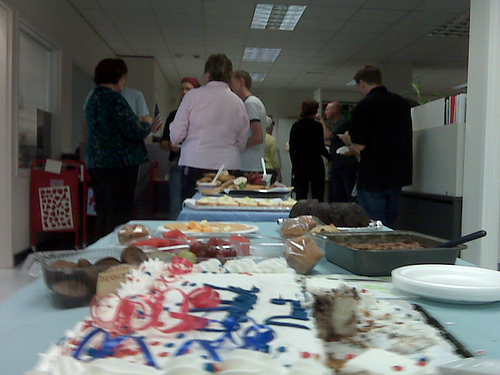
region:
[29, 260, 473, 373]
a white decorated sheet cake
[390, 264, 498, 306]
a stack of disposable plates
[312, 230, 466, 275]
a square metal pan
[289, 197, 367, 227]
a chocolate bundt cake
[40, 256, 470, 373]
a half eaten cake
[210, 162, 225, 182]
a white plastic utensil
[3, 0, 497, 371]
standing people in office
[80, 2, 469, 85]
row of lights on ceiling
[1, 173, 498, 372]
two tables covered with food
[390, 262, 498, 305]
stack of white styrofoam plates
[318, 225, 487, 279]
utensil in square metal pan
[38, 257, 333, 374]
cake with white frosting and cut edge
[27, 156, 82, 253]
side of red cart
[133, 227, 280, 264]
fruit in clear plastic tray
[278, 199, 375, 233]
side of chocolate bundt cake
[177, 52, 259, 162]
person standing at party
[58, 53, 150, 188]
person standing at party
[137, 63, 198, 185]
person standing at party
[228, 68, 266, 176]
person standing at party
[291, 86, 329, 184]
person standing at party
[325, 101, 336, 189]
person standing at party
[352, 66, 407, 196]
person standing at party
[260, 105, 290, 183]
person standing at party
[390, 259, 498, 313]
the plates are white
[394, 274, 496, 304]
stack of white plates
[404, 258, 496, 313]
white plates are foam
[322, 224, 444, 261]
grey pan on table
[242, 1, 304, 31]
fluorescent lights on ceiling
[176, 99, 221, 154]
woman has pink shirt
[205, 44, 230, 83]
woman has brown hair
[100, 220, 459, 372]
blue cloth on table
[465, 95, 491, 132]
white wall near table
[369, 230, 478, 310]
a pan on a table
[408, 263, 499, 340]
plates on a table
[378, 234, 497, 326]
plates stacked on a table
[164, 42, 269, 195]
a person standing inside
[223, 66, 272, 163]
a person standing inside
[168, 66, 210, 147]
a person standing inside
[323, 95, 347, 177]
a person standing inside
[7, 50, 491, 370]
tables of food in front of people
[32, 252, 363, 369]
white cake with blue and red ribbons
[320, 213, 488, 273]
dark pan of brownies with utensil sticking out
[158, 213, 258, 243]
cheese cubes with brown crackers on plate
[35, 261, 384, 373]
Partially cut sheet cake on the table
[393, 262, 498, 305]
styrofoam plates on the table.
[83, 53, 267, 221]
People standing in a circle talking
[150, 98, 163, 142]
American flag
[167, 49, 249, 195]
Woman wearing a light pink jacket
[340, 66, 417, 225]
Man wearing a black shirt and blue jeans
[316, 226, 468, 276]
Pan of food on the table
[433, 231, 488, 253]
Handle of utensil sticking out of platter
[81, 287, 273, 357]
Swirly red and blue streamers on the cake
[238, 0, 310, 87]
Lights in the ceiling.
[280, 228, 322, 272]
a muffin in a plastic bag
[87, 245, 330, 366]
a cake with white frosting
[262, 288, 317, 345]
blue writing on a cake